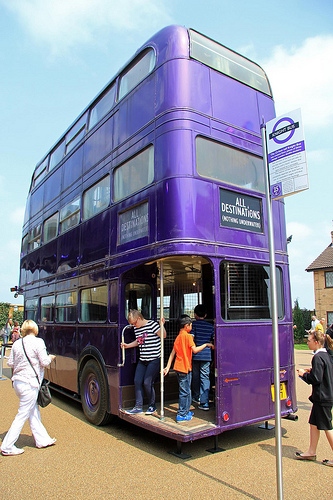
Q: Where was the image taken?
A: It was taken at the road.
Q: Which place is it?
A: It is a road.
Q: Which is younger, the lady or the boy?
A: The boy is younger than the lady.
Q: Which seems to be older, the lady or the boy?
A: The lady is older than the boy.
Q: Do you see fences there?
A: No, there are no fences.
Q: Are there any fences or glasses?
A: No, there are no fences or glasses.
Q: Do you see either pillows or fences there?
A: No, there are no fences or pillows.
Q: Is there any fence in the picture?
A: No, there are no fences.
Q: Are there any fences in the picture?
A: No, there are no fences.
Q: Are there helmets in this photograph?
A: No, there are no helmets.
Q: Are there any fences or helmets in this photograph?
A: No, there are no helmets or fences.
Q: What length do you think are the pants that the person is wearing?
A: The trousers are long.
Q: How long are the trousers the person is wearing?
A: The trousers are long.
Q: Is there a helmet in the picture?
A: No, there are no helmets.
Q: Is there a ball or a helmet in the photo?
A: No, there are no helmets or balls.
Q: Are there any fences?
A: No, there are no fences.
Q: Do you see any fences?
A: No, there are no fences.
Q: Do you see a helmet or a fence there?
A: No, there are no fences or helmets.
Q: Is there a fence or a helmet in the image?
A: No, there are no fences or helmets.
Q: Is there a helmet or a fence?
A: No, there are no fences or helmets.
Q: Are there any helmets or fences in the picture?
A: No, there are no fences or helmets.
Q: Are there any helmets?
A: No, there are no helmets.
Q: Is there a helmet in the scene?
A: No, there are no helmets.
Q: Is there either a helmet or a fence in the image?
A: No, there are no helmets or fences.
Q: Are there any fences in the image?
A: No, there are no fences.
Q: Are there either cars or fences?
A: No, there are no fences or cars.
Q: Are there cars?
A: No, there are no cars.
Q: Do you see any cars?
A: No, there are no cars.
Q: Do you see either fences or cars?
A: No, there are no cars or fences.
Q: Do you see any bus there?
A: Yes, there is a bus.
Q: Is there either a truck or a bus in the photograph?
A: Yes, there is a bus.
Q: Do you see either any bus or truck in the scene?
A: Yes, there is a bus.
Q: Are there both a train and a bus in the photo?
A: No, there is a bus but no trains.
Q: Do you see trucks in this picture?
A: No, there are no trucks.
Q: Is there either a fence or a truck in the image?
A: No, there are no trucks or fences.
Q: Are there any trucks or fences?
A: No, there are no trucks or fences.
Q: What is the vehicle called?
A: The vehicle is a bus.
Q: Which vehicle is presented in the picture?
A: The vehicle is a bus.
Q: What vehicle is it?
A: The vehicle is a bus.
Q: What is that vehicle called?
A: That is a bus.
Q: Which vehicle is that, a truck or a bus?
A: That is a bus.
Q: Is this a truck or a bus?
A: This is a bus.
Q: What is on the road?
A: The bus is on the road.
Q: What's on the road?
A: The bus is on the road.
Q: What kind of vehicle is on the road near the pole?
A: The vehicle is a bus.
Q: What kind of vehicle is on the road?
A: The vehicle is a bus.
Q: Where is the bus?
A: The bus is on the road.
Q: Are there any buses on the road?
A: Yes, there is a bus on the road.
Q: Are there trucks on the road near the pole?
A: No, there is a bus on the road.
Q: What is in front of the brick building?
A: The bus is in front of the building.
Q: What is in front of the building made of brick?
A: The bus is in front of the building.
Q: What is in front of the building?
A: The bus is in front of the building.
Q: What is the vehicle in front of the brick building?
A: The vehicle is a bus.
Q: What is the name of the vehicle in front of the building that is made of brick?
A: The vehicle is a bus.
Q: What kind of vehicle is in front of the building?
A: The vehicle is a bus.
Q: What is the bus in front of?
A: The bus is in front of the building.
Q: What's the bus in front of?
A: The bus is in front of the building.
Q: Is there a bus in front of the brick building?
A: Yes, there is a bus in front of the building.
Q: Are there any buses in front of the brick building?
A: Yes, there is a bus in front of the building.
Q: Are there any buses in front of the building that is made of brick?
A: Yes, there is a bus in front of the building.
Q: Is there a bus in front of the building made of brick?
A: Yes, there is a bus in front of the building.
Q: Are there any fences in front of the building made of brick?
A: No, there is a bus in front of the building.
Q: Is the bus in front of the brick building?
A: Yes, the bus is in front of the building.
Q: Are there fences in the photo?
A: No, there are no fences.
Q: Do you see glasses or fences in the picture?
A: No, there are no fences or glasses.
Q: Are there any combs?
A: No, there are no combs.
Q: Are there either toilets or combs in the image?
A: No, there are no combs or toilets.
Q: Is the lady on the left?
A: Yes, the lady is on the left of the image.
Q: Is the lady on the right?
A: No, the lady is on the left of the image.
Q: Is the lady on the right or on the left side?
A: The lady is on the left of the image.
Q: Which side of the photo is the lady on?
A: The lady is on the left of the image.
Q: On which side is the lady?
A: The lady is on the left of the image.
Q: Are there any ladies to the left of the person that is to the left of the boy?
A: Yes, there is a lady to the left of the person.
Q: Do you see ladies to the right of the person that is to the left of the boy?
A: No, the lady is to the left of the person.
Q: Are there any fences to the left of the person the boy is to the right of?
A: No, there is a lady to the left of the person.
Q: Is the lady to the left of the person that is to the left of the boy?
A: Yes, the lady is to the left of the person.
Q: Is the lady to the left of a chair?
A: No, the lady is to the left of the person.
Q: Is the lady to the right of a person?
A: No, the lady is to the left of a person.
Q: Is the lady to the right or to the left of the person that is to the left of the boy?
A: The lady is to the left of the person.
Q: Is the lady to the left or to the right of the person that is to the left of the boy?
A: The lady is to the left of the person.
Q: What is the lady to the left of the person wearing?
A: The lady is wearing a shirt.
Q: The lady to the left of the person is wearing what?
A: The lady is wearing a shirt.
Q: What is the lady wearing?
A: The lady is wearing a shirt.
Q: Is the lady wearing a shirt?
A: Yes, the lady is wearing a shirt.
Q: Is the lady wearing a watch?
A: No, the lady is wearing a shirt.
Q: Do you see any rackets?
A: No, there are no rackets.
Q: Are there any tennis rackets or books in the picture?
A: No, there are no tennis rackets or books.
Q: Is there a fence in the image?
A: No, there are no fences.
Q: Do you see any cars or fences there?
A: No, there are no fences or cars.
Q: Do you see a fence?
A: No, there are no fences.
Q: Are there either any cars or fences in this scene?
A: No, there are no fences or cars.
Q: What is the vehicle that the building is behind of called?
A: The vehicle is a bus.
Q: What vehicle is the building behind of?
A: The building is behind the bus.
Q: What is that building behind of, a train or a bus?
A: The building is behind a bus.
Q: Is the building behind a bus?
A: Yes, the building is behind a bus.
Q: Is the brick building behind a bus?
A: Yes, the building is behind a bus.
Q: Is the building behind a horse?
A: No, the building is behind a bus.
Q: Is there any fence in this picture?
A: No, there are no fences.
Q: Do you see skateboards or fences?
A: No, there are no fences or skateboards.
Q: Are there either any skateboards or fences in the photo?
A: No, there are no fences or skateboards.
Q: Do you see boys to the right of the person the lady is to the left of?
A: Yes, there is a boy to the right of the person.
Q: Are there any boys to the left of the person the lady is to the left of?
A: No, the boy is to the right of the person.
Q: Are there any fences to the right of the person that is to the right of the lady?
A: No, there is a boy to the right of the person.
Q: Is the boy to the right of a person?
A: Yes, the boy is to the right of a person.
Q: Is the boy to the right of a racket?
A: No, the boy is to the right of a person.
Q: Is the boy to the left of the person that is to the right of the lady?
A: No, the boy is to the right of the person.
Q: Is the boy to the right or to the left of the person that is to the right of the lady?
A: The boy is to the right of the person.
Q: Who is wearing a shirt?
A: The boy is wearing a shirt.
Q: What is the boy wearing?
A: The boy is wearing a shirt.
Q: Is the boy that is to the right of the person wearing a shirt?
A: Yes, the boy is wearing a shirt.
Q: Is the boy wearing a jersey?
A: No, the boy is wearing a shirt.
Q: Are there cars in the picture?
A: No, there are no cars.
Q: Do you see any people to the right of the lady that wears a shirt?
A: Yes, there is a person to the right of the lady.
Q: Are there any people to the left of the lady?
A: No, the person is to the right of the lady.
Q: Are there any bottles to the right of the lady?
A: No, there is a person to the right of the lady.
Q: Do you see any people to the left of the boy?
A: Yes, there is a person to the left of the boy.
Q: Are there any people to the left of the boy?
A: Yes, there is a person to the left of the boy.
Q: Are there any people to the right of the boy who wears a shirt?
A: No, the person is to the left of the boy.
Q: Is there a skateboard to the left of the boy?
A: No, there is a person to the left of the boy.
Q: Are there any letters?
A: Yes, there are letters.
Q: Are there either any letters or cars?
A: Yes, there are letters.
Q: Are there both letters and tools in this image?
A: No, there are letters but no tools.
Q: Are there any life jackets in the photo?
A: No, there are no life jackets.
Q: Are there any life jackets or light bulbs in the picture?
A: No, there are no life jackets or light bulbs.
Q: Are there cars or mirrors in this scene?
A: No, there are no cars or mirrors.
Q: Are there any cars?
A: No, there are no cars.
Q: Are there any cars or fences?
A: No, there are no cars or fences.